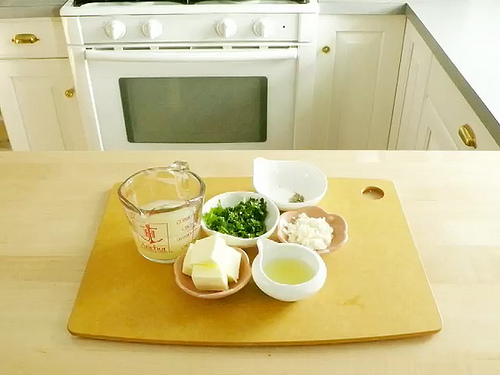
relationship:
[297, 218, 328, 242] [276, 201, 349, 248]
rice in bowl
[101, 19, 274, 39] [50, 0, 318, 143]
knobs on stove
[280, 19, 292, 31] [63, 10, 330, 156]
light on front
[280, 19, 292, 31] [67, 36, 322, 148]
light on oven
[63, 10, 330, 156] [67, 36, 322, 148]
front of oven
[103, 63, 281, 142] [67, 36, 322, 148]
front of oven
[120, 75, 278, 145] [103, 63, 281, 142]
window on front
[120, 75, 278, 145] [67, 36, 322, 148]
window on oven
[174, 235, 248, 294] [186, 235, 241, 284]
bowl filled with butter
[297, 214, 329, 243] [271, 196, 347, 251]
onion in bowl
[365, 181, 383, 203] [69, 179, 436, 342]
hole in cutting board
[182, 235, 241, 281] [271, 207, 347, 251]
butter in bowl